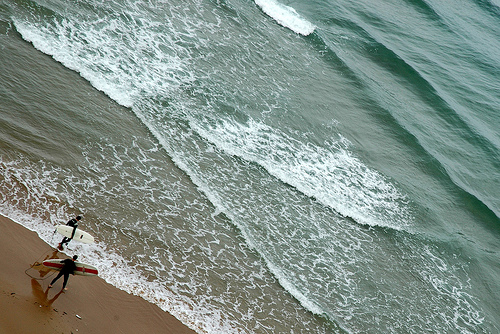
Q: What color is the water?
A: Teal.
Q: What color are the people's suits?
A: Black.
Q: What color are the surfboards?
A: Red and white.